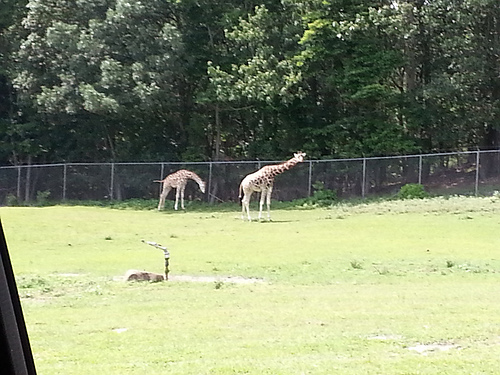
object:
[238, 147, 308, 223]
giraffe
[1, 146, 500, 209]
fence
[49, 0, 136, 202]
trees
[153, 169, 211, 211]
giraffe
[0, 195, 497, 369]
grass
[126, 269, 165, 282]
rock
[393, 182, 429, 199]
bush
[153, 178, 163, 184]
tail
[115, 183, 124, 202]
tree trunk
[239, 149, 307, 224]
giraffes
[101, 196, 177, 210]
shrubs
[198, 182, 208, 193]
giraffe head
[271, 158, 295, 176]
neck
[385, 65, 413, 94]
branches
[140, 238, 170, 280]
pipe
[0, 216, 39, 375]
window edge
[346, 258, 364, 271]
tufts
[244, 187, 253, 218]
giraffe's leg